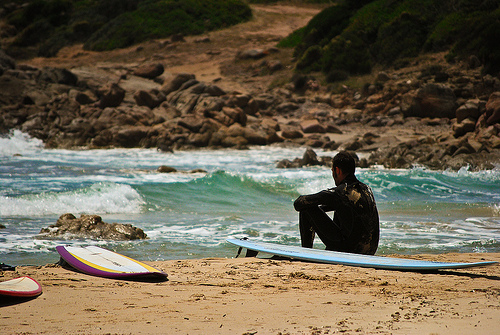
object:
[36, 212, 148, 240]
rock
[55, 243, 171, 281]
boogie board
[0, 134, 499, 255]
water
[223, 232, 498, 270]
surfboard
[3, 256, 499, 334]
beach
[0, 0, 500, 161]
hill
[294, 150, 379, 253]
surfer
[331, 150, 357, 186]
head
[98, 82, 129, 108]
rocks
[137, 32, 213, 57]
dirt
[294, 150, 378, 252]
man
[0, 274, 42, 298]
surfboard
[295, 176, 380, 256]
wetsuit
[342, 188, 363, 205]
sand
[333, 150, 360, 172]
hair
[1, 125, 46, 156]
spray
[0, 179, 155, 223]
wave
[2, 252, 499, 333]
shore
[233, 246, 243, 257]
fin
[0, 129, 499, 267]
ocean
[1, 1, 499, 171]
shore